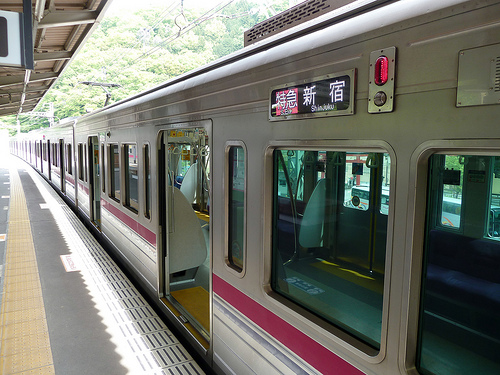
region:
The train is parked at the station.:
[70, 111, 484, 373]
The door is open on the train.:
[132, 128, 207, 333]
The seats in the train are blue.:
[410, 236, 494, 306]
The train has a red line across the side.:
[212, 284, 316, 361]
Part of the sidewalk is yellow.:
[7, 203, 48, 364]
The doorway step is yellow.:
[178, 281, 218, 331]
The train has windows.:
[91, 135, 151, 204]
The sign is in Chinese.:
[266, 83, 361, 125]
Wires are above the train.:
[113, 13, 197, 85]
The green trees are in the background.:
[103, 26, 165, 81]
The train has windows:
[16, 121, 351, 289]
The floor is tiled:
[0, 224, 81, 369]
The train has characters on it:
[239, 63, 373, 144]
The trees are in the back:
[62, 26, 277, 153]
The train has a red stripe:
[78, 181, 163, 285]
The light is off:
[359, 41, 416, 134]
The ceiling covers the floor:
[2, 6, 109, 188]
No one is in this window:
[259, 135, 439, 363]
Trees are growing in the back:
[6, 13, 243, 160]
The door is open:
[134, 124, 249, 371]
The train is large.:
[18, 126, 493, 208]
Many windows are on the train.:
[30, 123, 495, 374]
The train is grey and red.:
[18, 97, 488, 369]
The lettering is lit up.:
[258, 49, 418, 143]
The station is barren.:
[3, 153, 135, 373]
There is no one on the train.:
[35, 128, 497, 374]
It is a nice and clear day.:
[13, 14, 495, 374]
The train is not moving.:
[10, 10, 496, 374]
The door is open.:
[153, 124, 217, 356]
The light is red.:
[366, 44, 400, 116]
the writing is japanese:
[231, 49, 418, 159]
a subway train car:
[97, 89, 344, 373]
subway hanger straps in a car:
[134, 100, 248, 206]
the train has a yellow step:
[148, 223, 266, 360]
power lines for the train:
[76, 70, 171, 135]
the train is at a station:
[8, 57, 215, 302]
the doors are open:
[69, 95, 411, 363]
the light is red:
[367, 57, 431, 116]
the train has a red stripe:
[91, 128, 178, 285]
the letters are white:
[234, 67, 486, 163]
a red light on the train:
[369, 54, 391, 89]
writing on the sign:
[264, 70, 352, 120]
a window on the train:
[218, 139, 250, 274]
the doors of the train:
[151, 122, 229, 359]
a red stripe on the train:
[205, 263, 378, 373]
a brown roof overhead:
[0, 1, 113, 121]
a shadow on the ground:
[16, 167, 135, 374]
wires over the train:
[0, 0, 234, 131]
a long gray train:
[4, 0, 499, 374]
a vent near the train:
[41, 179, 203, 373]